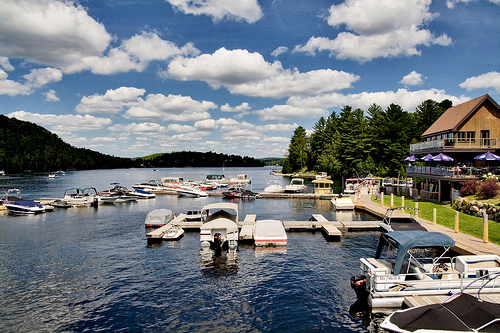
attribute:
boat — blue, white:
[349, 231, 498, 311]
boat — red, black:
[223, 178, 268, 205]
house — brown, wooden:
[400, 90, 499, 205]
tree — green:
[287, 124, 312, 171]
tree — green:
[323, 119, 345, 176]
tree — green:
[342, 122, 376, 165]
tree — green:
[373, 100, 410, 177]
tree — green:
[408, 87, 451, 134]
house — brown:
[410, 94, 499, 196]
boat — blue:
[201, 202, 241, 250]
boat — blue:
[280, 174, 308, 194]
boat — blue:
[351, 229, 498, 324]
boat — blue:
[5, 191, 60, 216]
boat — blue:
[137, 171, 194, 202]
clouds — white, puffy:
[0, 0, 500, 157]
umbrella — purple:
[397, 153, 418, 165]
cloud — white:
[166, 46, 363, 96]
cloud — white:
[398, 69, 428, 86]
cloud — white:
[166, 0, 264, 25]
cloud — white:
[295, 29, 451, 61]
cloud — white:
[326, 2, 444, 36]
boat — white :
[192, 200, 249, 252]